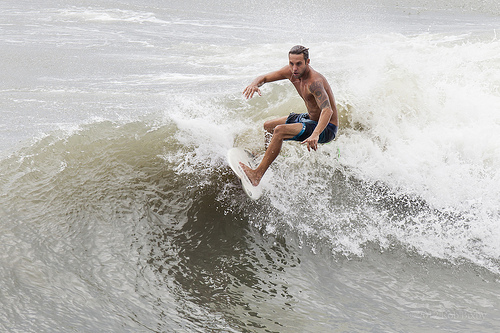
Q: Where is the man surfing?
A: In the ocean.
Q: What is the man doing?
A: Surfing.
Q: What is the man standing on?
A: A surfboard.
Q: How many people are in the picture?
A: 1.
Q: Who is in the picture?
A: A man.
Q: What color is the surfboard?
A: White.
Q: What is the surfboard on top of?
A: A wave.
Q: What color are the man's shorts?
A: Blue.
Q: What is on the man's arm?
A: A tattoo.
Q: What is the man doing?
A: Surfing.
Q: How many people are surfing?
A: One.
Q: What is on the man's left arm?
A: Tattoos.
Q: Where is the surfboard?
A: In the water.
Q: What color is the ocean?
A: Gray.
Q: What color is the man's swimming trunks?
A: Blue.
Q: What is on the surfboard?
A: The man.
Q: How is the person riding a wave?
A: On a surfboard.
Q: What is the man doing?
A: Surfing.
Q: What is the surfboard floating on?
A: A wave.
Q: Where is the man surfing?
A: The ocean.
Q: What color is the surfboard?
A: White.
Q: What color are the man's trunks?
A: Blue.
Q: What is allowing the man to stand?
A: Surf board.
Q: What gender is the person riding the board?
A: Male.